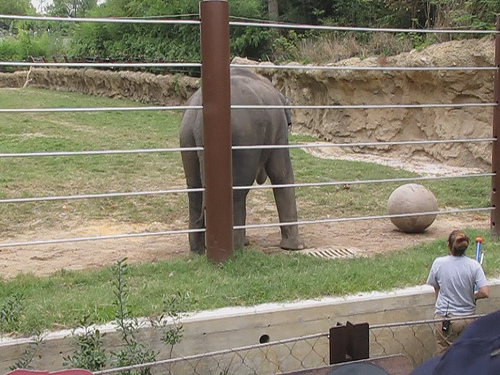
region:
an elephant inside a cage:
[176, 55, 340, 264]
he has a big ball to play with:
[365, 167, 447, 239]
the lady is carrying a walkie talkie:
[428, 217, 485, 373]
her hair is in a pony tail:
[445, 228, 478, 275]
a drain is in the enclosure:
[290, 250, 365, 260]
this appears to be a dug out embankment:
[308, 84, 474, 174]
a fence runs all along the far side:
[39, 53, 204, 88]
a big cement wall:
[16, 278, 439, 373]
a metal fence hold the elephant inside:
[7, 58, 410, 231]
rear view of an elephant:
[175, 66, 307, 256]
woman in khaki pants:
[425, 227, 490, 352]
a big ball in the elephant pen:
[385, 181, 437, 231]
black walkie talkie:
[440, 296, 451, 333]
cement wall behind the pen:
[0, 277, 495, 372]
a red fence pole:
[200, 0, 235, 262]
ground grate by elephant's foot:
[296, 242, 356, 257]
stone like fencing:
[0, 70, 195, 101]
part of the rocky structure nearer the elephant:
[272, 40, 494, 165]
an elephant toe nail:
[296, 240, 303, 248]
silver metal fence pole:
[227, 18, 496, 39]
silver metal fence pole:
[232, 57, 492, 82]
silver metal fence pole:
[232, 99, 492, 111]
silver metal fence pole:
[230, 131, 494, 148]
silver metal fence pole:
[233, 170, 493, 192]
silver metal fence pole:
[233, 204, 496, 234]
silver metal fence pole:
[0, 55, 202, 71]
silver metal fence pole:
[0, 100, 202, 124]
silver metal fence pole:
[2, 148, 205, 164]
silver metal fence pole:
[6, 181, 203, 204]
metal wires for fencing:
[231, 13, 499, 43]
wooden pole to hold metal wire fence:
[198, 0, 240, 262]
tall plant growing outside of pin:
[81, 262, 186, 373]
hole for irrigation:
[257, 333, 273, 347]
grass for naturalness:
[143, 256, 330, 293]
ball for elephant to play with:
[388, 180, 436, 231]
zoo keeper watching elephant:
[428, 227, 488, 316]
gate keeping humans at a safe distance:
[221, 321, 433, 356]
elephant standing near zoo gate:
[178, 62, 305, 249]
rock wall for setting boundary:
[321, 55, 485, 165]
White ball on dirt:
[385, 182, 440, 229]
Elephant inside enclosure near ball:
[144, 49, 298, 250]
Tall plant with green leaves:
[75, 258, 182, 365]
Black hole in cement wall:
[257, 335, 269, 342]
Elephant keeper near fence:
[432, 228, 489, 342]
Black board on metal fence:
[325, 315, 377, 361]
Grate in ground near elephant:
[307, 247, 369, 262]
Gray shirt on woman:
[425, 253, 483, 307]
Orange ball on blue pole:
[475, 234, 484, 240]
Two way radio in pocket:
[440, 300, 450, 331]